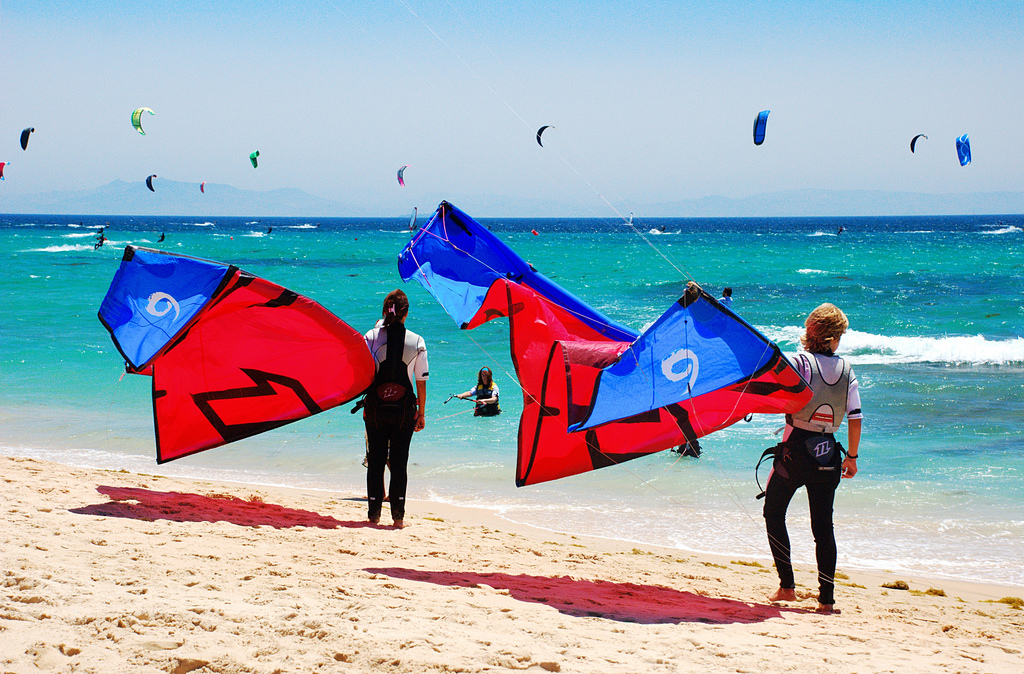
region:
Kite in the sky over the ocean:
[897, 120, 937, 162]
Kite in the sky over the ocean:
[745, 105, 783, 144]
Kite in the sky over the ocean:
[531, 116, 570, 173]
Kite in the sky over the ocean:
[389, 157, 413, 195]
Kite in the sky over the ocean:
[246, 146, 270, 166]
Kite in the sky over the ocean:
[196, 176, 209, 195]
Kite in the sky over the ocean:
[139, 165, 163, 195]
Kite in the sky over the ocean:
[125, 107, 161, 128]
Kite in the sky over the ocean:
[18, 123, 50, 147]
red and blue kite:
[106, 235, 342, 471]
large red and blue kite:
[417, 205, 776, 510]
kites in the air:
[35, 87, 999, 209]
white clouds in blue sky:
[468, 121, 507, 169]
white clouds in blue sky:
[596, 170, 644, 213]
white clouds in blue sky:
[622, 65, 702, 120]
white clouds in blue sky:
[698, 33, 768, 73]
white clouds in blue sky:
[812, 151, 864, 194]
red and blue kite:
[420, 191, 759, 496]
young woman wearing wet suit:
[354, 289, 443, 533]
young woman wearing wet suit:
[767, 287, 873, 616]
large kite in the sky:
[5, 104, 62, 169]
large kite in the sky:
[101, 91, 159, 137]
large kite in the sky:
[132, 148, 168, 199]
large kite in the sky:
[228, 118, 287, 177]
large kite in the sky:
[496, 103, 588, 155]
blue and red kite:
[97, 243, 369, 453]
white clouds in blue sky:
[214, 43, 259, 69]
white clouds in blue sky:
[430, 74, 482, 117]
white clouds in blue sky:
[807, 168, 858, 207]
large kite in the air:
[112, 89, 167, 144]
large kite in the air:
[512, 102, 558, 167]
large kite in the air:
[719, 87, 793, 182]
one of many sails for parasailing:
[392, 193, 820, 495]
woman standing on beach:
[348, 282, 432, 532]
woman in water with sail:
[439, 361, 503, 422]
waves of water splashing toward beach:
[720, 313, 1022, 372]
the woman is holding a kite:
[109, 234, 391, 460]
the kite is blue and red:
[106, 243, 385, 460]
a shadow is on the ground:
[83, 480, 358, 539]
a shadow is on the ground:
[368, 550, 786, 630]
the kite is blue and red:
[406, 187, 806, 492]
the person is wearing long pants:
[762, 426, 855, 591]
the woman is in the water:
[452, 363, 506, 417]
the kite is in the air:
[747, 105, 771, 143]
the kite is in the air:
[533, 121, 553, 145]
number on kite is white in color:
[640, 291, 727, 431]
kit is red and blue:
[415, 171, 821, 525]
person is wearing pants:
[763, 397, 900, 633]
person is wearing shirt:
[772, 332, 880, 434]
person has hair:
[792, 300, 856, 340]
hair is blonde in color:
[789, 291, 850, 364]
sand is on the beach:
[26, 426, 900, 662]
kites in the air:
[58, 72, 1014, 265]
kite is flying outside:
[533, 121, 547, 151]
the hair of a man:
[789, 306, 844, 358]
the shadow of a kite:
[430, 534, 675, 671]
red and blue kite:
[75, 228, 377, 470]